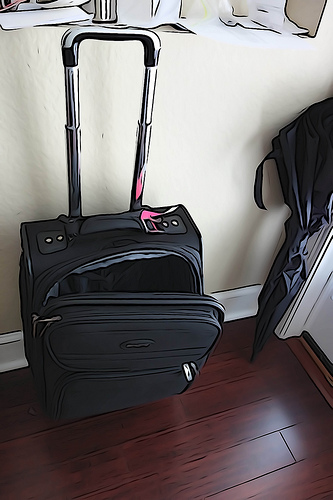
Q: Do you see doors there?
A: Yes, there is a door.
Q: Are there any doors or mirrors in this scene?
A: Yes, there is a door.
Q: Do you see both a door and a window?
A: No, there is a door but no windows.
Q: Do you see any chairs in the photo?
A: No, there are no chairs.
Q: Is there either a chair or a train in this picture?
A: No, there are no chairs or trains.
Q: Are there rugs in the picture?
A: No, there are no rugs.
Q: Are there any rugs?
A: No, there are no rugs.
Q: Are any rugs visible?
A: No, there are no rugs.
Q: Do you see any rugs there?
A: No, there are no rugs.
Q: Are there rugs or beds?
A: No, there are no rugs or beds.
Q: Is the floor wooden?
A: Yes, the floor is wooden.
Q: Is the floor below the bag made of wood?
A: Yes, the floor is made of wood.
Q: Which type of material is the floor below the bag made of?
A: The floor is made of wood.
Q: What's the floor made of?
A: The floor is made of wood.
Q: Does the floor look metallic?
A: No, the floor is wooden.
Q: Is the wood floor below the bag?
A: Yes, the floor is below the bag.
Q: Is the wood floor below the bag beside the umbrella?
A: Yes, the floor is below the bag.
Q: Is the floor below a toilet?
A: No, the floor is below the bag.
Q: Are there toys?
A: No, there are no toys.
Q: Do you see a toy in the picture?
A: No, there are no toys.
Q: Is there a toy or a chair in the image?
A: No, there are no toys or chairs.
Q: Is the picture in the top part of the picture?
A: Yes, the picture is in the top of the image.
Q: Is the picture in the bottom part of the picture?
A: No, the picture is in the top of the image.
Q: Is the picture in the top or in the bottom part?
A: The picture is in the top of the image.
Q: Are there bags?
A: Yes, there is a bag.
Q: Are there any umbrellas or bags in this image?
A: Yes, there is a bag.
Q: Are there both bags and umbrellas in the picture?
A: Yes, there are both a bag and an umbrella.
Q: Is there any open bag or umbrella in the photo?
A: Yes, there is an open bag.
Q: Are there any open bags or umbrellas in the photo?
A: Yes, there is an open bag.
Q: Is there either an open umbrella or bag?
A: Yes, there is an open bag.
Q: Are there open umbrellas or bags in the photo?
A: Yes, there is an open bag.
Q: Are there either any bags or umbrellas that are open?
A: Yes, the bag is open.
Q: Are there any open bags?
A: Yes, there is an open bag.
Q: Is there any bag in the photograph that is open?
A: Yes, there is a bag that is open.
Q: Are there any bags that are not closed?
A: Yes, there is a open bag.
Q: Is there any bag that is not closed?
A: Yes, there is a open bag.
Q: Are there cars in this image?
A: No, there are no cars.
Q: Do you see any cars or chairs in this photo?
A: No, there are no cars or chairs.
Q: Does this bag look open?
A: Yes, the bag is open.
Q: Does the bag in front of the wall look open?
A: Yes, the bag is open.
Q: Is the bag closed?
A: No, the bag is open.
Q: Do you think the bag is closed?
A: No, the bag is open.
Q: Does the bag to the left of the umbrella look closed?
A: No, the bag is open.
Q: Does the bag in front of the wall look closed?
A: No, the bag is open.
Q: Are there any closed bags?
A: No, there is a bag but it is open.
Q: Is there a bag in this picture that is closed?
A: No, there is a bag but it is open.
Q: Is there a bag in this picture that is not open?
A: No, there is a bag but it is open.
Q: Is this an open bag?
A: Yes, this is an open bag.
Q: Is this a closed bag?
A: No, this is an open bag.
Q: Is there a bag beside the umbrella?
A: Yes, there is a bag beside the umbrella.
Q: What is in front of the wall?
A: The bag is in front of the wall.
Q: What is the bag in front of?
A: The bag is in front of the wall.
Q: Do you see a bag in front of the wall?
A: Yes, there is a bag in front of the wall.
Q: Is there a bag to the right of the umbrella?
A: No, the bag is to the left of the umbrella.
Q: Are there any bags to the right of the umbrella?
A: No, the bag is to the left of the umbrella.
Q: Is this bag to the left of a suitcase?
A: No, the bag is to the left of an umbrella.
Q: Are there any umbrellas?
A: Yes, there is an umbrella.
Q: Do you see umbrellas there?
A: Yes, there is an umbrella.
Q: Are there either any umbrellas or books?
A: Yes, there is an umbrella.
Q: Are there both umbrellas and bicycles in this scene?
A: No, there is an umbrella but no bikes.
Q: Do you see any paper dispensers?
A: No, there are no paper dispensers.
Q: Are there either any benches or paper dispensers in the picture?
A: No, there are no paper dispensers or benches.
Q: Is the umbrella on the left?
A: No, the umbrella is on the right of the image.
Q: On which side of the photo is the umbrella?
A: The umbrella is on the right of the image.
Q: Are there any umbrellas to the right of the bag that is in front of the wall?
A: Yes, there is an umbrella to the right of the bag.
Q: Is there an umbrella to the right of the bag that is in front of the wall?
A: Yes, there is an umbrella to the right of the bag.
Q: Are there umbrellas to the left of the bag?
A: No, the umbrella is to the right of the bag.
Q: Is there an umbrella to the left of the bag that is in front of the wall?
A: No, the umbrella is to the right of the bag.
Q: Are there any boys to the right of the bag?
A: No, there is an umbrella to the right of the bag.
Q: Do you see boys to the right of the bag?
A: No, there is an umbrella to the right of the bag.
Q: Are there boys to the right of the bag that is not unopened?
A: No, there is an umbrella to the right of the bag.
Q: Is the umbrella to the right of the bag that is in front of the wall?
A: Yes, the umbrella is to the right of the bag.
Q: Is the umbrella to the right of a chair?
A: No, the umbrella is to the right of the bag.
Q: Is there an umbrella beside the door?
A: Yes, there is an umbrella beside the door.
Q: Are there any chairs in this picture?
A: No, there are no chairs.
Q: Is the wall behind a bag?
A: Yes, the wall is behind a bag.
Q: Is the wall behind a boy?
A: No, the wall is behind a bag.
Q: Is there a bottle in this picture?
A: No, there are no bottles.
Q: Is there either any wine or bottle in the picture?
A: No, there are no bottles or wine.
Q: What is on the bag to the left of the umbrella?
A: The label is on the bag.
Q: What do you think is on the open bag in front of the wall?
A: The label is on the bag.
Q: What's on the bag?
A: The label is on the bag.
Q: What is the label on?
A: The label is on the bag.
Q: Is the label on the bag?
A: Yes, the label is on the bag.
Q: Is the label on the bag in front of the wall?
A: Yes, the label is on the bag.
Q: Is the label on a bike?
A: No, the label is on the bag.